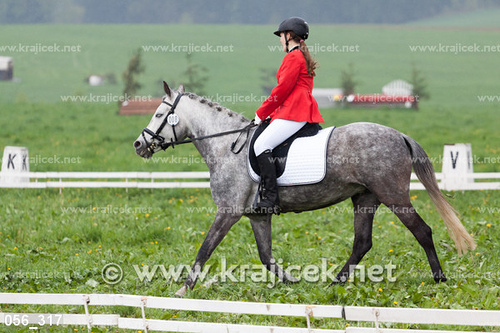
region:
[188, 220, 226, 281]
leg of a horse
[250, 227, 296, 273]
leg of a horse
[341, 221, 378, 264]
leg of a horse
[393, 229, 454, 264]
leg of a horse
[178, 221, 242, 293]
a leg of a horse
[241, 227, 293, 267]
a leg of a horse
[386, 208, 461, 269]
a leg of a horse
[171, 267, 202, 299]
feet of a horse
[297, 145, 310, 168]
white saddle on horse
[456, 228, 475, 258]
end of horse tail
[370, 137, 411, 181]
butt of grey horse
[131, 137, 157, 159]
horse mouth is closed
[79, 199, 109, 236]
green grass in field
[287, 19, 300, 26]
woman wearing black hat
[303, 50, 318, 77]
woman has long hair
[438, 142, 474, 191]
white marker by the side of a field labeled V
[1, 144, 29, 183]
white marker by the side of a field labled K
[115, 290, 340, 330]
strip of white fence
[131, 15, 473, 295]
woman riding a horse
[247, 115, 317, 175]
fancy black dress saddle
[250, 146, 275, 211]
black colored riding boots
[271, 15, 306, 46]
black riding helmet on a head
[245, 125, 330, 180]
white blanket under a saddle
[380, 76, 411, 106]
white building in a field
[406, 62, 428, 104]
tall tree in a field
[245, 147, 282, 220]
Woman wearing black shoes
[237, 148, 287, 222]
Woman is wearing black shoes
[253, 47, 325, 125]
Woman wearing a coat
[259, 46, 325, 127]
Woman wearing a red coat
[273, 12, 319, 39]
Woman is wearing a black helmet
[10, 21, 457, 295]
this is a horse rider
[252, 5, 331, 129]
this is a woman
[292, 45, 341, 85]
the woman has brown hair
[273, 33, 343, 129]
the jacket is red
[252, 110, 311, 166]
the pants are white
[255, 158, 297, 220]
these are boots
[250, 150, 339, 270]
the boots are black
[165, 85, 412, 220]
this is a horse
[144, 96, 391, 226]
the horse is gray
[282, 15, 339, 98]
the woman has a ponytail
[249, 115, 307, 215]
the womans legs below torso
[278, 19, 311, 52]
the womans head above shoulders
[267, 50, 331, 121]
the womans shirt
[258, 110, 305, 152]
the womans pants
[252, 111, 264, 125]
the womans hand at end of arm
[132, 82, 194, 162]
head of the horse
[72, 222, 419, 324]
a watermark on bottom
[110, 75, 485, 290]
a gray horse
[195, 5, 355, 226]
a rider on a horse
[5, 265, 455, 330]
a white fence in forefront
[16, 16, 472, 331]
scene outside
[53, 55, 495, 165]
buildings in the background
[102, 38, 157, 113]
a green tree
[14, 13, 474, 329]
a scene during the day time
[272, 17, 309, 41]
helmet is black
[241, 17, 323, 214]
girl is riding horse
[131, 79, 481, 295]
horse is walking in grass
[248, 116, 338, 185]
seat is on the horses back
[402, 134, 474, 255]
tail is apart of the horse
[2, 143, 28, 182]
sign has a k on it